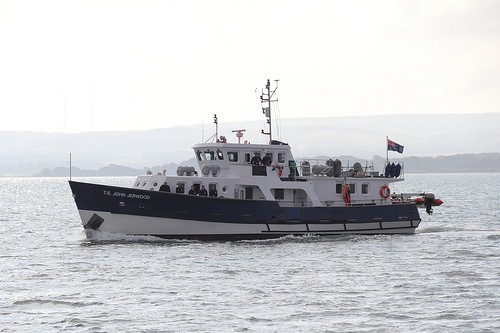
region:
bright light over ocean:
[1, 0, 496, 130]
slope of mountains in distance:
[0, 110, 496, 170]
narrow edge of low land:
[40, 147, 490, 172]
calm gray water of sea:
[5, 175, 495, 325]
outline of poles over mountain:
[55, 70, 90, 135]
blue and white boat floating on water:
[61, 75, 441, 245]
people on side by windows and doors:
[140, 170, 222, 200]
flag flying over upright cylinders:
[376, 130, 406, 180]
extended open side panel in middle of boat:
[226, 170, 321, 210]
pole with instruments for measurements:
[252, 68, 287, 141]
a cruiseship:
[62, 72, 446, 243]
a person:
[246, 149, 265, 162]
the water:
[207, 258, 390, 329]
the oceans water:
[113, 258, 273, 322]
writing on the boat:
[96, 186, 147, 204]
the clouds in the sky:
[336, 35, 446, 97]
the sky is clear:
[321, 35, 441, 100]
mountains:
[30, 128, 75, 149]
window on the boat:
[360, 182, 367, 192]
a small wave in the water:
[15, 284, 95, 310]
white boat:
[44, 91, 429, 249]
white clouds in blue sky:
[14, 12, 72, 64]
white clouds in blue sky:
[68, 48, 139, 116]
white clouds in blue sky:
[34, 71, 84, 126]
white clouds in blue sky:
[121, 32, 189, 94]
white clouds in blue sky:
[310, 26, 370, 84]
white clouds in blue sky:
[377, 18, 457, 65]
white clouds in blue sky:
[341, 46, 413, 106]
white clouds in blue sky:
[400, 51, 492, 108]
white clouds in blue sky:
[290, 23, 351, 63]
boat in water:
[44, 81, 449, 246]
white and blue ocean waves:
[368, 263, 432, 310]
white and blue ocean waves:
[264, 271, 305, 298]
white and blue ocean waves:
[314, 246, 364, 311]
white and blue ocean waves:
[208, 272, 279, 316]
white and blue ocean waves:
[155, 263, 195, 307]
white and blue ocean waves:
[85, 278, 140, 310]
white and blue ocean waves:
[311, 265, 361, 293]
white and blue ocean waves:
[458, 242, 498, 260]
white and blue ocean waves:
[200, 253, 241, 303]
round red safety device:
[379, 183, 391, 198]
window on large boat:
[358, 180, 373, 193]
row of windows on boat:
[333, 178, 371, 195]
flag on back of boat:
[383, 125, 405, 162]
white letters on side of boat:
[99, 188, 156, 203]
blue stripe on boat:
[166, 196, 241, 218]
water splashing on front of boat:
[80, 230, 149, 242]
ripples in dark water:
[450, 188, 487, 205]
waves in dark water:
[13, 291, 106, 310]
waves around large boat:
[238, 231, 320, 243]